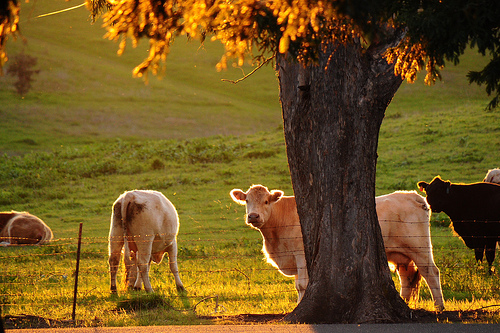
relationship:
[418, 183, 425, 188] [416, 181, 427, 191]
tag on ear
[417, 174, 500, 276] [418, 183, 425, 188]
cow has tag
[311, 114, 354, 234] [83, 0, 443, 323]
bark on tree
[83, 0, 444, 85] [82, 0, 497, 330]
leaves on tree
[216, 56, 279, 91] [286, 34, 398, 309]
branch on tree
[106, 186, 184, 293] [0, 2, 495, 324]
cow in field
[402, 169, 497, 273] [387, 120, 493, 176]
cow in field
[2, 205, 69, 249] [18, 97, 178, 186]
cow in field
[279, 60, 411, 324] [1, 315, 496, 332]
bark on ground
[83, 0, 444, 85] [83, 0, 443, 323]
leaves on tree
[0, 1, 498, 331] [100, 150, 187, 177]
grass on ground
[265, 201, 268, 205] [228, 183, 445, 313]
eye on beige cow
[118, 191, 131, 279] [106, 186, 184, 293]
tail on cow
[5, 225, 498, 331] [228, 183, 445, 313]
wire fence around beige cow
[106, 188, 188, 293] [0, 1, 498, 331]
cow eating grass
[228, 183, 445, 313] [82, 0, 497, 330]
beige cow next to tree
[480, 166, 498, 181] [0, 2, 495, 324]
cow in field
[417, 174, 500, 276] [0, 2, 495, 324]
cow in field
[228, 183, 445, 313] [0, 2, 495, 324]
beige cow in field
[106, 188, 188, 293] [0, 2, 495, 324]
cow in field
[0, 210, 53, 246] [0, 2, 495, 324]
cow in field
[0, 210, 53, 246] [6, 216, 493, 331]
cow behind wire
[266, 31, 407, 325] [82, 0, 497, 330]
trunk of tree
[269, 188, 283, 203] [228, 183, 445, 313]
ear of beige cow